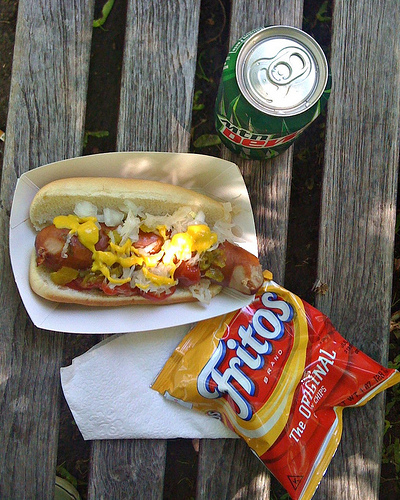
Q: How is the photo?
A: Clear.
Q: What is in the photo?
A: Food.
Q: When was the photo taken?
A: Daytime.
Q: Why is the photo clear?
A: Its during the day.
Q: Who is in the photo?
A: Nobody.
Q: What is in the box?
A: Hotdog.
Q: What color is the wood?
A: Brown.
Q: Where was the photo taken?
A: On a park table.